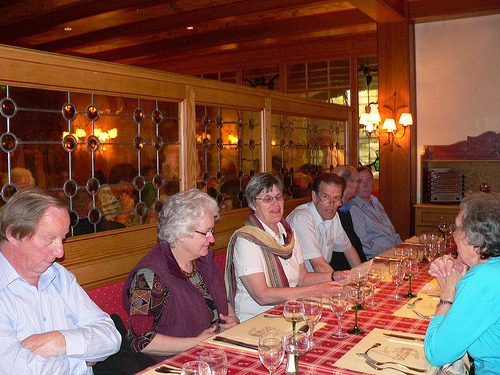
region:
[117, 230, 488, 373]
red and pink table cloth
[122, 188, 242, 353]
woman in purple vest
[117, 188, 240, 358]
gray haired woman with glasses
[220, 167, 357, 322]
woman with salt and pepper hair and glasses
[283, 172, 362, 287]
man with white shirt and glasses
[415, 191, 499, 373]
woman with aqua blue shirt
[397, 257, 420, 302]
wine glass with green stem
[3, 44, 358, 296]
wood and glass divider wall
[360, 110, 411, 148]
electric light sconces on wall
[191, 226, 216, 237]
a woman's eyeglasses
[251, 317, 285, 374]
a tall wine glass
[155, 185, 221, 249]
a woman's gray hair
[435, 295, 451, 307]
part of a woman's watch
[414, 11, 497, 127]
a white painted wall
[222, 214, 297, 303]
part of a woman's scarf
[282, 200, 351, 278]
part of a man's white shirt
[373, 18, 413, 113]
part of a brown wall trim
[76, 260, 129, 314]
part of a bench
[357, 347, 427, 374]
two long forks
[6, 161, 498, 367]
people sitting at a table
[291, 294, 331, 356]
glasses on a table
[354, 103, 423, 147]
illuminated lights on a wall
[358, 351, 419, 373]
utensils on a table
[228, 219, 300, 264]
scarf on a woman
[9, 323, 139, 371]
arms crossed on a man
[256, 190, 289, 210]
glasses on a woman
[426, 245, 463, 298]
folded hands of a woman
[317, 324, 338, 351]
red plaid tablecloth on a table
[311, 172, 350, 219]
face of a man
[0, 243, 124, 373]
Man wearing a shirt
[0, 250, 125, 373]
Man is wearing a shirt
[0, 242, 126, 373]
Man wearing a blue shirt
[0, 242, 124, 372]
Man is wearing a blue shirt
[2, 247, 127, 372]
Man wearing a light blue shirt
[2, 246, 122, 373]
Man is wearing a light blue shirt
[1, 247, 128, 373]
Man wearing a dress shirt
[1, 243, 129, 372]
Man is wearing a dress shirt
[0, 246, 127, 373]
Man wearing a light blue dress shirt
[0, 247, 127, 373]
Man is wearing a light blue dress shirt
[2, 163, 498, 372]
group of people sitting at a dinner table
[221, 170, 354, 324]
woman wearing a scarf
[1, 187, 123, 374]
man taking a nap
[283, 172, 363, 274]
man wearing glasses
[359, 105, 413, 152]
light fixture lit up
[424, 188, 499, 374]
old lady wearing a blue shirt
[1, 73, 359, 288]
glass and wooden divider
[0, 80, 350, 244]
decorative colored glass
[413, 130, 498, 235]
wooden cabnit and shelf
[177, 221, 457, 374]
Dinner glasses on table